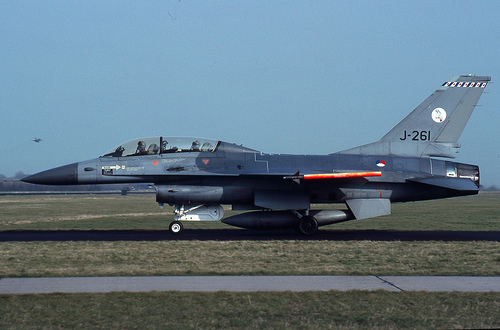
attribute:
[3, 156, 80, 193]
nose — gunmetal gray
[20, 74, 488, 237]
jet — dark grey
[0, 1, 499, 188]
sky — clear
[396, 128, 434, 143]
number — black